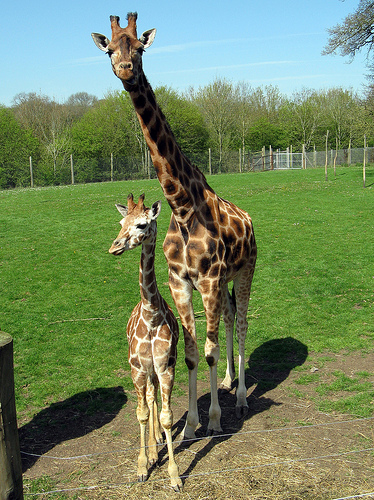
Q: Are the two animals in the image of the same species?
A: Yes, all the animals are giraffes.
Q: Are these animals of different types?
A: No, all the animals are giraffes.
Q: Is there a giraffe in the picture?
A: Yes, there is a giraffe.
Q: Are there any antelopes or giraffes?
A: Yes, there is a giraffe.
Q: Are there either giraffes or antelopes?
A: Yes, there is a giraffe.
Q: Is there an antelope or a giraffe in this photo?
A: Yes, there is a giraffe.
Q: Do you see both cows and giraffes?
A: No, there is a giraffe but no cows.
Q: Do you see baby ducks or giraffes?
A: Yes, there is a baby giraffe.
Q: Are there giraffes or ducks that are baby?
A: Yes, the giraffe is a baby.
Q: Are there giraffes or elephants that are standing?
A: Yes, the giraffe is standing.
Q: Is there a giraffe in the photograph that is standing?
A: Yes, there is a giraffe that is standing.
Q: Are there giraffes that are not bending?
A: Yes, there is a giraffe that is standing.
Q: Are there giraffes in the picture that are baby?
A: Yes, there is a baby giraffe.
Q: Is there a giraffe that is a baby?
A: Yes, there is a giraffe that is a baby.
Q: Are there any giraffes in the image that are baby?
A: Yes, there is a giraffe that is a baby.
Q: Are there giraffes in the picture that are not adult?
A: Yes, there is an baby giraffe.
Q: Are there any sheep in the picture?
A: No, there are no sheep.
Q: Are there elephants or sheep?
A: No, there are no sheep or elephants.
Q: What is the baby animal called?
A: The animal is a giraffe.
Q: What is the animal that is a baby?
A: The animal is a giraffe.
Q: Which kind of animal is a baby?
A: The animal is a giraffe.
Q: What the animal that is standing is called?
A: The animal is a giraffe.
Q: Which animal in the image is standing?
A: The animal is a giraffe.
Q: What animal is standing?
A: The animal is a giraffe.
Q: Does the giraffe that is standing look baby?
A: Yes, the giraffe is a baby.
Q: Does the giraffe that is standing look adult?
A: No, the giraffe is a baby.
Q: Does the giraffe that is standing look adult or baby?
A: The giraffe is a baby.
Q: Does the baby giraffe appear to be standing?
A: Yes, the giraffe is standing.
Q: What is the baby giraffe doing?
A: The giraffe is standing.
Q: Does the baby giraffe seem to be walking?
A: No, the giraffe is standing.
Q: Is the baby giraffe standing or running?
A: The giraffe is standing.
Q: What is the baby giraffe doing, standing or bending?
A: The giraffe is standing.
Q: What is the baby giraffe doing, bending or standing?
A: The giraffe is standing.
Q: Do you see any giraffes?
A: Yes, there is a giraffe.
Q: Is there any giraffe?
A: Yes, there is a giraffe.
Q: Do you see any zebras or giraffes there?
A: Yes, there is a giraffe.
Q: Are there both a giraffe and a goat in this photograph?
A: No, there is a giraffe but no goats.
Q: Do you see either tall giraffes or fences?
A: Yes, there is a tall giraffe.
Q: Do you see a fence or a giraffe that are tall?
A: Yes, the giraffe is tall.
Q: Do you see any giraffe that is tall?
A: Yes, there is a tall giraffe.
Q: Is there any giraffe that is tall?
A: Yes, there is a giraffe that is tall.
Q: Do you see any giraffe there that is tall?
A: Yes, there is a giraffe that is tall.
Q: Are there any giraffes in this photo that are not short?
A: Yes, there is a tall giraffe.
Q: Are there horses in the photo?
A: No, there are no horses.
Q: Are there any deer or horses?
A: No, there are no horses or deer.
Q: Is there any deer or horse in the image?
A: No, there are no horses or deer.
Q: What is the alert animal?
A: The animal is a giraffe.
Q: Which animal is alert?
A: The animal is a giraffe.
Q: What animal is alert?
A: The animal is a giraffe.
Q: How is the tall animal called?
A: The animal is a giraffe.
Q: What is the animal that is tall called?
A: The animal is a giraffe.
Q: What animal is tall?
A: The animal is a giraffe.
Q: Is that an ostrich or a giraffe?
A: That is a giraffe.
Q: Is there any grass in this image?
A: Yes, there is grass.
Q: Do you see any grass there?
A: Yes, there is grass.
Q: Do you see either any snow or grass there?
A: Yes, there is grass.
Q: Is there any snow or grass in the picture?
A: Yes, there is grass.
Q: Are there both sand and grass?
A: No, there is grass but no sand.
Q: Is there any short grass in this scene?
A: Yes, there is short grass.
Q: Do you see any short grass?
A: Yes, there is short grass.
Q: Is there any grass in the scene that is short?
A: Yes, there is grass that is short.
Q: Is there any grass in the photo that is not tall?
A: Yes, there is short grass.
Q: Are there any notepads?
A: No, there are no notepads.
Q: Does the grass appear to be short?
A: Yes, the grass is short.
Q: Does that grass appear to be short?
A: Yes, the grass is short.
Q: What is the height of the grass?
A: The grass is short.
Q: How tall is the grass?
A: The grass is short.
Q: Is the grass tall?
A: No, the grass is short.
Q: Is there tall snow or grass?
A: No, there is grass but it is short.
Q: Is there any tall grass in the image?
A: No, there is grass but it is short.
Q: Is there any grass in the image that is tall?
A: No, there is grass but it is short.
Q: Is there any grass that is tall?
A: No, there is grass but it is short.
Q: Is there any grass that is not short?
A: No, there is grass but it is short.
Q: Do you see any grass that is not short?
A: No, there is grass but it is short.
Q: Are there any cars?
A: No, there are no cars.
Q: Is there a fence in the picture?
A: Yes, there is a fence.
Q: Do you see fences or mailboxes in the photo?
A: Yes, there is a fence.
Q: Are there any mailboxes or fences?
A: Yes, there is a fence.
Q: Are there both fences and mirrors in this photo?
A: No, there is a fence but no mirrors.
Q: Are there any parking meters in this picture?
A: No, there are no parking meters.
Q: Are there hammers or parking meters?
A: No, there are no parking meters or hammers.